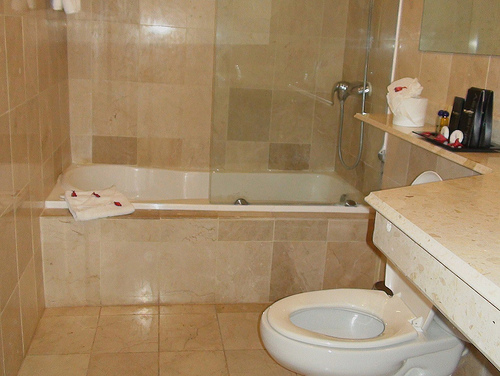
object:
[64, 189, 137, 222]
towel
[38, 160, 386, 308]
tub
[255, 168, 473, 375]
toilet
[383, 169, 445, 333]
lid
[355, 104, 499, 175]
shelf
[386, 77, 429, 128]
toilet paper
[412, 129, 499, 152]
tray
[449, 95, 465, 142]
toiletries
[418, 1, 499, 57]
mirror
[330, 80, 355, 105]
shower head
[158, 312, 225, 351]
tile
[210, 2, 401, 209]
shower door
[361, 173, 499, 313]
countertop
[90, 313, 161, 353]
floor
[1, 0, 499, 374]
bathroom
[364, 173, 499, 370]
counter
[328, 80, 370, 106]
faucet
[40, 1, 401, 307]
shower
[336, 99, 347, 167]
hose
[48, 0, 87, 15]
towel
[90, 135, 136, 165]
tiles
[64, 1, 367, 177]
wall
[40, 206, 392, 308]
exterior of the tub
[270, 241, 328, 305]
tile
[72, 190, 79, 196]
adornments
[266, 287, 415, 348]
seat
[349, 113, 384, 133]
edge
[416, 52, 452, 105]
section